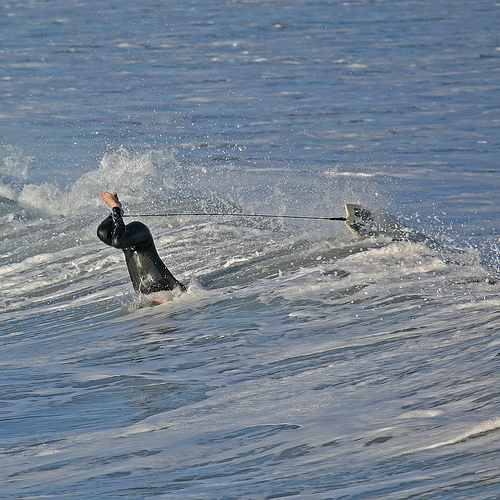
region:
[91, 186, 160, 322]
person has black wetsuit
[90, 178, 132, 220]
person has bare feet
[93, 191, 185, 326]
person diving in water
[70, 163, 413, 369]
few waves next to person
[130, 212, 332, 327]
water is clear near person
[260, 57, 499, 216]
water is calm behind person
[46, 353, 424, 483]
water is calm in front of person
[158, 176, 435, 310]
small white-cap waves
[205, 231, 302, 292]
surfboard is overturned and yellow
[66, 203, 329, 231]
black cord near person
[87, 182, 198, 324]
person falling off surfboard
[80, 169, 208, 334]
person falling into water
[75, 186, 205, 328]
person wearing black wetsuit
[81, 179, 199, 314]
person with no footwear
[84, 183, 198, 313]
surfer with board attached to their foot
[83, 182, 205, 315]
person with surfboard attached to ankle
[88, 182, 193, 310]
person who is upside down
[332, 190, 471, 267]
black and white surfboard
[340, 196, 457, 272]
surfboard falling into the water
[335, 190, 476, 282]
surfboard attached to surfer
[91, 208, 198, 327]
a person in the water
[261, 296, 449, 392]
the water is blue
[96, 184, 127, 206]
a persons feet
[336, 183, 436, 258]
a surfbord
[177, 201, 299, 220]
a black string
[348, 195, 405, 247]
the surfboard is white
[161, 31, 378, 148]
the water is blue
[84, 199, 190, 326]
person is swimming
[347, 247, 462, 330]
water is white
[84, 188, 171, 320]
Man swimming in the ocean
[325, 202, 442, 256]
Surf Board in the water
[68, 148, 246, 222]
Ocean waves crashing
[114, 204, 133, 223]
Surf board tied to a man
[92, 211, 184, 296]
Man wearing a black and grey swimsuit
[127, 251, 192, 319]
Man upside down in the water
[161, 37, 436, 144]
Blue ocean water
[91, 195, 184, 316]
Man swimming upside down in ocean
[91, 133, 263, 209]
Water spraying from crashing waves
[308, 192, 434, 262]
White surf board crashing in ocean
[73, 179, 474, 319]
man upside down in water with surf board behind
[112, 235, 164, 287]
shiny black and gray wetsuit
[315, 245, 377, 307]
water splashing out of the ocean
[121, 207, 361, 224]
cord between surfer and board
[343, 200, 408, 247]
white surf board with blue design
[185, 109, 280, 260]
small waves in ocean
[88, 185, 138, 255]
bare feet sticking out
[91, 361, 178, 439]
clear light blue water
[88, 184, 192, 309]
surfer upside down in water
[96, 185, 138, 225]
cord attached to board tied on man's ankle